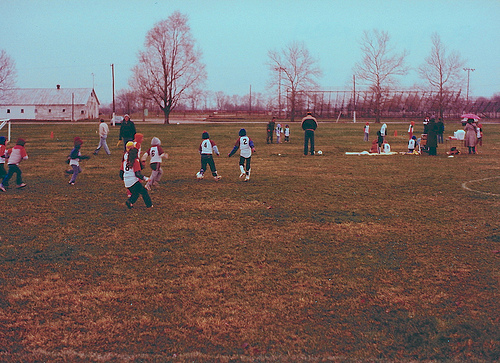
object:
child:
[228, 127, 257, 181]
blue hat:
[238, 128, 246, 137]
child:
[196, 130, 221, 179]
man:
[300, 106, 317, 156]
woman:
[463, 117, 478, 154]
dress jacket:
[463, 122, 477, 149]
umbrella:
[459, 112, 481, 121]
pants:
[127, 180, 151, 207]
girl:
[123, 147, 153, 209]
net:
[0, 119, 12, 142]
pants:
[71, 166, 79, 180]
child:
[0, 136, 30, 190]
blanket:
[342, 149, 399, 156]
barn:
[0, 84, 102, 122]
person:
[362, 122, 369, 141]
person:
[407, 135, 415, 151]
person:
[141, 135, 169, 191]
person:
[62, 137, 89, 186]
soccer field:
[0, 123, 499, 362]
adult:
[116, 114, 138, 162]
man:
[266, 116, 276, 146]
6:
[149, 150, 155, 157]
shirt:
[141, 145, 169, 164]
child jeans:
[2, 163, 22, 186]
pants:
[303, 130, 315, 155]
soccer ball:
[195, 170, 207, 178]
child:
[283, 124, 291, 143]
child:
[274, 123, 284, 145]